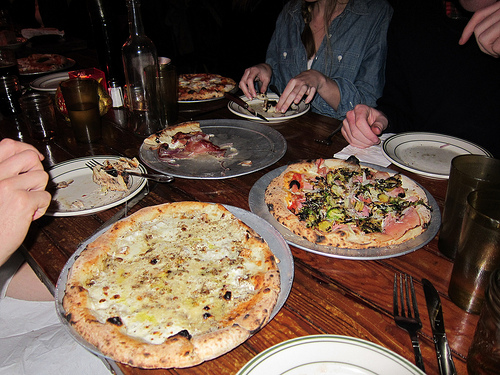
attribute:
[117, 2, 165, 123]
bottle — empty, clear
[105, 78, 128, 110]
salt shaker — small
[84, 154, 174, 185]
fork — small, metal, shiny, bright, silver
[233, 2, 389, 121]
woman — eating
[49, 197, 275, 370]
pizza — ready, large, round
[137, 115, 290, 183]
pan — round, large, silver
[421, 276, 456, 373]
butter knife — silver 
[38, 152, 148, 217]
plate — clear, empty, white, small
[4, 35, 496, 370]
table — wide, brown, wooden, large